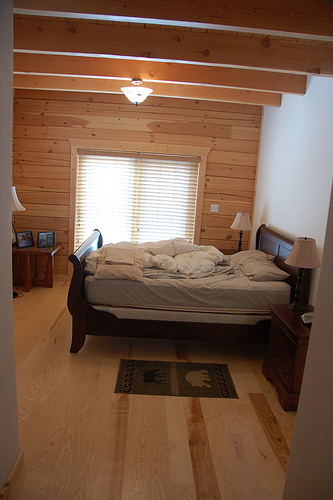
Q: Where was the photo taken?
A: A room.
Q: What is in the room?
A: A bed.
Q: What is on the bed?
A: Pillows.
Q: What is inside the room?
A: A window.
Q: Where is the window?
A: Next to bed.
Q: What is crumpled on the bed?
A: Comforter.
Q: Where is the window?
A: Behind the bed.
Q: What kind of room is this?
A: Bedroom.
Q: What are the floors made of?
A: Wood.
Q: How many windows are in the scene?
A: One.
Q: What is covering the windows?
A: Blinds.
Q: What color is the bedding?
A: White.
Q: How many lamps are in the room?
A: Three.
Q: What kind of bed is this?
A: Sleigh bed.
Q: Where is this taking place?
A: In a cabin.